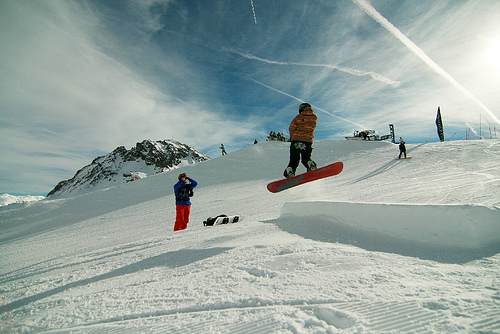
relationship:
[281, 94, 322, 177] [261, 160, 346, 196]
person on snowboard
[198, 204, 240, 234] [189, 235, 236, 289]
snowboard on ground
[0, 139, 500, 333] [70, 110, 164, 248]
snow covered mountain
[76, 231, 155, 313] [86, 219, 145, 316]
snow covering ground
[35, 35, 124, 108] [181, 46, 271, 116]
clouds covering sky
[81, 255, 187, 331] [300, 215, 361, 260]
tracks made in snow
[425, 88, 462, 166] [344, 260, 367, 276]
flag in snow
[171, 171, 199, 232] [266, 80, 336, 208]
people watching snowboarder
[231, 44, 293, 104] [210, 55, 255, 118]
lines in sky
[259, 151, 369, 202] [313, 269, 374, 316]
snowboard jump in snow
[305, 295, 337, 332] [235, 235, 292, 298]
print in snow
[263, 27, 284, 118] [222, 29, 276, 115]
streaks across sky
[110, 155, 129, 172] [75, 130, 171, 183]
snow covered mountain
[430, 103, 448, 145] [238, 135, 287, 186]
flag on hill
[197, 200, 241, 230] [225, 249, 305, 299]
bag of snow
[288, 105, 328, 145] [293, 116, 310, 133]
jacket with lines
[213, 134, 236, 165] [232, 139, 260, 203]
skier skiing down hill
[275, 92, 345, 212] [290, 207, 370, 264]
skier doing tricks in snow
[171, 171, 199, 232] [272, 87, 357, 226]
people taking picture of snowboarder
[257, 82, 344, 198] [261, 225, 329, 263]
snowboarder in snow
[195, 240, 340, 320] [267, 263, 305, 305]
ground covered in snow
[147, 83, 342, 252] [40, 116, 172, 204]
people snowboarding on mountain